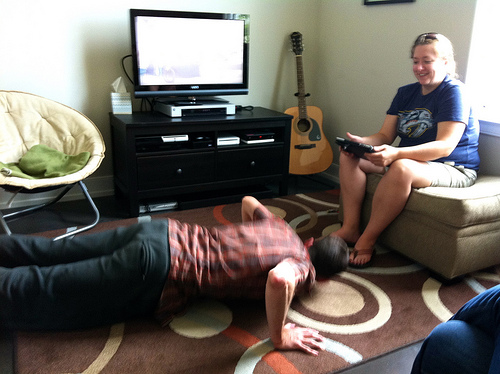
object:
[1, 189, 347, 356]
man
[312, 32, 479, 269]
woman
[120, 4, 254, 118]
tv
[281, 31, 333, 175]
guitar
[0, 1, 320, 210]
wall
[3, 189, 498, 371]
floor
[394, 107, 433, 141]
symbol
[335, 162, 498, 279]
sofa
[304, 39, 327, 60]
corner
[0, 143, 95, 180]
pillow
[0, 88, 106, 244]
chair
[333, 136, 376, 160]
tablet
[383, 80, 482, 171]
shirt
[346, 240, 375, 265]
foot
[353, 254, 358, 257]
thong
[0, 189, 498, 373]
rug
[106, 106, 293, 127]
counter